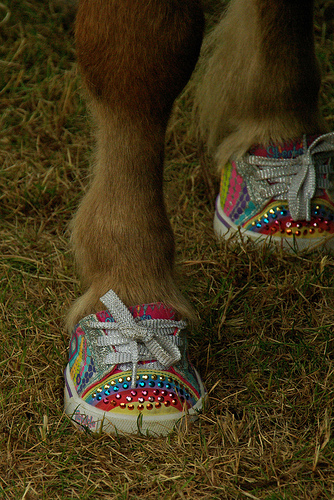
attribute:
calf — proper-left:
[80, 76, 176, 263]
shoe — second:
[210, 131, 332, 250]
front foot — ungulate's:
[211, 129, 332, 251]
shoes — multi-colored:
[63, 121, 331, 435]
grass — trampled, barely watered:
[0, 418, 330, 497]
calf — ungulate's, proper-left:
[66, 10, 190, 168]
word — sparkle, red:
[71, 405, 97, 428]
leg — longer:
[215, 8, 303, 149]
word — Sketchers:
[266, 143, 305, 157]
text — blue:
[264, 144, 302, 159]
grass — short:
[0, 0, 332, 498]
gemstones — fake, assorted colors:
[85, 368, 197, 413]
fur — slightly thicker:
[216, 37, 289, 114]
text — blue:
[68, 405, 94, 427]